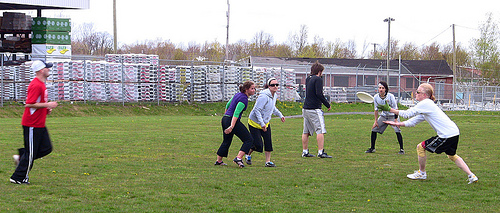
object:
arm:
[230, 96, 248, 127]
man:
[300, 59, 333, 159]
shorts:
[301, 109, 327, 137]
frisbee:
[356, 92, 375, 104]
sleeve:
[252, 97, 267, 128]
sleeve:
[314, 79, 330, 108]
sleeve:
[398, 105, 423, 119]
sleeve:
[25, 84, 43, 105]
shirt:
[398, 97, 461, 138]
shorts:
[421, 135, 460, 156]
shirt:
[373, 93, 398, 117]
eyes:
[271, 84, 279, 87]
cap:
[30, 59, 54, 75]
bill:
[46, 62, 53, 68]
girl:
[381, 82, 479, 185]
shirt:
[303, 74, 331, 109]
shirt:
[247, 88, 284, 130]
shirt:
[223, 92, 249, 119]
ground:
[0, 100, 500, 212]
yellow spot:
[367, 199, 371, 202]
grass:
[0, 99, 500, 213]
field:
[0, 100, 500, 213]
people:
[364, 81, 406, 155]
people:
[246, 76, 286, 168]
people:
[7, 59, 59, 186]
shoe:
[406, 170, 427, 180]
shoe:
[466, 173, 479, 185]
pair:
[405, 169, 480, 185]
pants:
[9, 125, 53, 184]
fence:
[0, 54, 500, 112]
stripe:
[20, 127, 35, 183]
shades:
[268, 83, 280, 87]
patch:
[416, 143, 426, 157]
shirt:
[20, 77, 50, 128]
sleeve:
[233, 98, 248, 118]